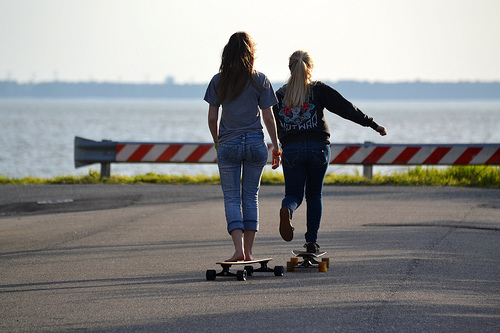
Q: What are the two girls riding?
A: Skateboards.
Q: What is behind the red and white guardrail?
A: Water.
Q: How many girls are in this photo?
A: Two.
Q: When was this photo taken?
A: Daytime.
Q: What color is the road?
A: Grey.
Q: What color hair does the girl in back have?
A: Brown.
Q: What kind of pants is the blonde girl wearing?
A: Blue Jeans.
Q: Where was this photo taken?
A: In a parking lot.